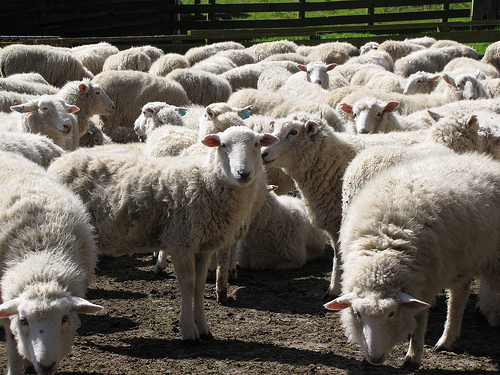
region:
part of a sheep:
[415, 168, 459, 225]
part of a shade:
[253, 328, 284, 355]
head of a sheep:
[361, 295, 386, 323]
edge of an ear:
[73, 297, 98, 319]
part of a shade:
[256, 338, 291, 368]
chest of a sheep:
[201, 182, 240, 281]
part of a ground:
[275, 305, 311, 338]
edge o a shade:
[237, 322, 266, 352]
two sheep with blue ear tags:
[145, 102, 275, 141]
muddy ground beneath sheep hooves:
[98, 269, 315, 374]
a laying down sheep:
[233, 172, 327, 270]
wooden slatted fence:
[6, 3, 495, 44]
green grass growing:
[225, 9, 487, 53]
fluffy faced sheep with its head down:
[320, 251, 433, 371]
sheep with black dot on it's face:
[6, 278, 75, 369]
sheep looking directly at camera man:
[205, 128, 274, 185]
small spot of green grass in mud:
[133, 304, 177, 338]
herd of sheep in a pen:
[2, 42, 494, 373]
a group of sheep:
[16, 37, 469, 352]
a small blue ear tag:
[232, 106, 256, 126]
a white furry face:
[195, 122, 281, 187]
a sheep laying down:
[193, 172, 337, 281]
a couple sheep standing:
[0, 131, 271, 362]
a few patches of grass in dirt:
[53, 246, 421, 366]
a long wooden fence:
[17, 0, 484, 41]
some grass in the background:
[248, 0, 483, 49]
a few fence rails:
[180, 5, 447, 37]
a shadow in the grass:
[186, 5, 255, 22]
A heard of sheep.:
[8, 38, 498, 373]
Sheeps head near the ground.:
[324, 273, 434, 368]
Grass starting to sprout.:
[132, 300, 177, 337]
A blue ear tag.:
[239, 108, 254, 123]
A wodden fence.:
[180, 1, 498, 44]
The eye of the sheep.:
[39, 106, 50, 113]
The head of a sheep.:
[299, 59, 339, 87]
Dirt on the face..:
[31, 324, 54, 337]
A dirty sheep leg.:
[214, 249, 229, 301]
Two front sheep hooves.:
[172, 326, 218, 345]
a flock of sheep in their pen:
[1, 33, 499, 366]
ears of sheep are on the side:
[193, 123, 278, 150]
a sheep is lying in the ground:
[250, 181, 330, 278]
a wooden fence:
[3, 5, 486, 41]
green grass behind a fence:
[194, 7, 482, 42]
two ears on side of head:
[0, 293, 104, 320]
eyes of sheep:
[16, 313, 73, 332]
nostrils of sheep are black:
[233, 166, 253, 177]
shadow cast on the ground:
[98, 323, 328, 368]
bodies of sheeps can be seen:
[10, 31, 497, 65]